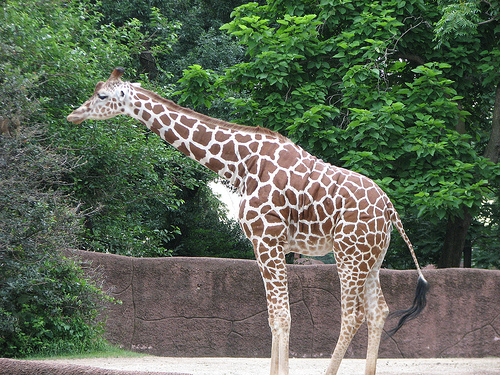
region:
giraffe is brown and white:
[51, 63, 433, 373]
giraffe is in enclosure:
[56, 64, 440, 374]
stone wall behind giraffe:
[56, 244, 497, 364]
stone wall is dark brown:
[50, 245, 499, 363]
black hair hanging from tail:
[384, 276, 431, 339]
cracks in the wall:
[86, 262, 219, 342]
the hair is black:
[404, 276, 437, 333]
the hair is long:
[398, 275, 422, 336]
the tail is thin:
[389, 210, 423, 291]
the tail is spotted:
[385, 199, 429, 287]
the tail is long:
[387, 205, 422, 287]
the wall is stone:
[80, 256, 352, 364]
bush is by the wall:
[4, 202, 228, 335]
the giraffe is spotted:
[80, 89, 414, 369]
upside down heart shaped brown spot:
[256, 155, 281, 183]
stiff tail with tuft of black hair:
[386, 207, 432, 337]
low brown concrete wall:
[53, 245, 497, 361]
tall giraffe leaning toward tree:
[63, 66, 433, 374]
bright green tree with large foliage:
[173, 1, 498, 223]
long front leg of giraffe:
[249, 230, 301, 374]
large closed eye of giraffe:
[93, 87, 115, 105]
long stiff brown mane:
[131, 78, 290, 142]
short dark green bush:
[4, 247, 128, 357]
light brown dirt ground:
[1, 354, 497, 374]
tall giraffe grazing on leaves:
[68, 64, 437, 372]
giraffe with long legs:
[57, 74, 422, 365]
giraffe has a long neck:
[71, 71, 427, 365]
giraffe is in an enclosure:
[17, 74, 475, 369]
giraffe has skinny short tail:
[401, 211, 436, 324]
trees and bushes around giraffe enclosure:
[37, 10, 493, 141]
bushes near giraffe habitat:
[3, 71, 121, 340]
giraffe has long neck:
[56, 73, 247, 187]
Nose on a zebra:
[59, 91, 117, 141]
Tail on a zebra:
[393, 219, 431, 352]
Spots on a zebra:
[244, 153, 330, 218]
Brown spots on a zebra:
[288, 167, 375, 257]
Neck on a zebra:
[126, 85, 243, 181]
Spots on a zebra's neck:
[126, 83, 289, 192]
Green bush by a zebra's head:
[1, 83, 115, 350]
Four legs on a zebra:
[241, 231, 414, 373]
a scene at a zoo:
[6, 7, 493, 373]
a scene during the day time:
[6, 5, 491, 367]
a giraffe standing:
[55, 52, 442, 374]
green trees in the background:
[3, 1, 498, 265]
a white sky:
[196, 168, 253, 233]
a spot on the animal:
[230, 136, 239, 145]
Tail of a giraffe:
[381, 196, 442, 345]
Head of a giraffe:
[58, 56, 150, 133]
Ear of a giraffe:
[115, 85, 129, 102]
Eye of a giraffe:
[93, 92, 111, 104]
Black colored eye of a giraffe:
[96, 90, 111, 102]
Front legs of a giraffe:
[247, 245, 307, 374]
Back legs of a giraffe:
[325, 259, 395, 374]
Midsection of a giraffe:
[252, 165, 341, 238]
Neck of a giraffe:
[139, 91, 259, 191]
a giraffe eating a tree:
[0, 68, 446, 372]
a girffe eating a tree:
[50, 28, 442, 373]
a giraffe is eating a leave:
[15, 30, 439, 374]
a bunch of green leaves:
[241, 10, 491, 118]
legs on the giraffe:
[255, 260, 415, 372]